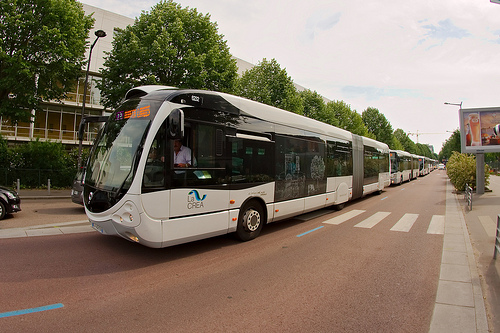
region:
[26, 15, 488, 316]
The buses are in a big city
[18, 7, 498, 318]
The buses are part of a fleet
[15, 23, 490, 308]
The buses are on the road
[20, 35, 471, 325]
The buses are carrying many passengers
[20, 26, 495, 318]
The buses are all very modern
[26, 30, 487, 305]
The buses all have good drivers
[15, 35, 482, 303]
The buses all have a sleek design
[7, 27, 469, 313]
The buses all have tinted windows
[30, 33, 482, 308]
The buses are running in daytime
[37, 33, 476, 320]
The buses are all brand new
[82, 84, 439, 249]
Group of city buses driving in a row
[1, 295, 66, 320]
Blue line between lanes on road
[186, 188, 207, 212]
Logo on side of bus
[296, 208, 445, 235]
Sidewalk in the middle of road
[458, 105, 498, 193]
Billboard on side of road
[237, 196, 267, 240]
Tire on side of bus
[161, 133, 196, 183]
Bus driver sitting inside bus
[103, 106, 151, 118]
Sign on front of bus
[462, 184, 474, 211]
Barrier on side of road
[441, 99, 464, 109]
Street light in the background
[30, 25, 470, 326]
The buses are a brand new fleet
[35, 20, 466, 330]
The buses are following each other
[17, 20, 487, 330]
The buses are in a city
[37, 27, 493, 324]
The buses are on the street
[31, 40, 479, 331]
The buses belong to the city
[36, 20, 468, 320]
The buses are all traveling safely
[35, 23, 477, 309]
The buses are operating in daytime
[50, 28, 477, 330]
The buses are for carrying commuters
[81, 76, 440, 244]
community buses double length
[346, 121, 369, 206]
center where the bus turns on a turntable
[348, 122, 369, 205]
accordian panel for flexibilty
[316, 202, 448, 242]
a white painted crosswalk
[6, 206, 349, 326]
blue lines down the center of the road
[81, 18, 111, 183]
a tall street light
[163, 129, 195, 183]
driver of the bus wears a white shirt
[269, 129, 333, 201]
adds posted to side of the bus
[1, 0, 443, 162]
a string of trees go down the road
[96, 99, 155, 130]
bus route and destination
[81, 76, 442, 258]
a long line of city buses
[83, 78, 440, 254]
a long line of white buses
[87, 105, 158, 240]
the front of a city bus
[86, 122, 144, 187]
the windshield of a bus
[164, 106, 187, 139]
the mirror of a bus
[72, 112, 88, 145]
the mirror of a bus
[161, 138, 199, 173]
the driver of a bus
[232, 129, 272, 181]
the windows of a bus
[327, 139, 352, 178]
the windows of a bus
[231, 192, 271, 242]
the wheel of a bus